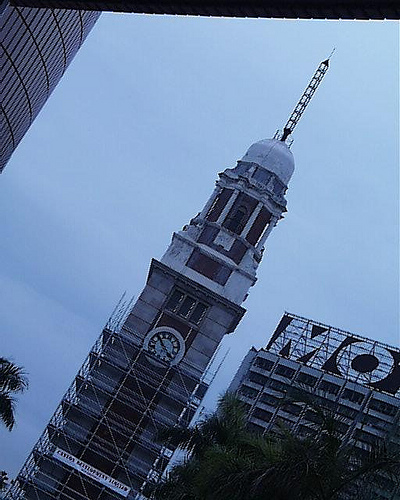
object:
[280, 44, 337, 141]
tip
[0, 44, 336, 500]
building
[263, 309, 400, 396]
letters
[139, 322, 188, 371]
clock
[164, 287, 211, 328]
windows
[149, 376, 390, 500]
tree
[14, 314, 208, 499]
stairs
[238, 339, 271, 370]
corner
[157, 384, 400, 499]
leaves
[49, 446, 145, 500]
banner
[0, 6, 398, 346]
sky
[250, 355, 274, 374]
window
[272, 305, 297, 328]
corner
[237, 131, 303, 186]
dome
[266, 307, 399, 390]
billboard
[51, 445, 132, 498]
letters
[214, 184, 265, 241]
pillars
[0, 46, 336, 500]
clocktower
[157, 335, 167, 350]
hand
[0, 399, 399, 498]
foreground